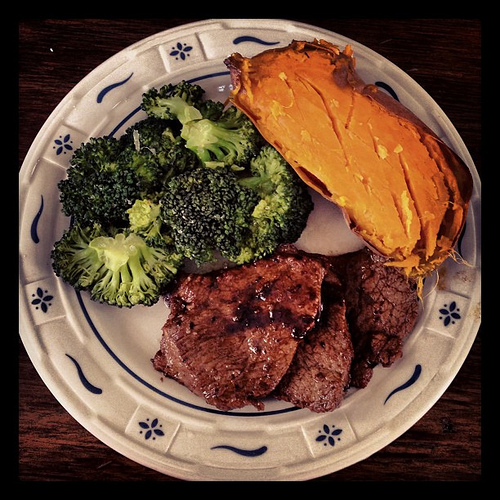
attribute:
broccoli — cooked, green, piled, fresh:
[44, 78, 319, 313]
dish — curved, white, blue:
[17, 16, 488, 486]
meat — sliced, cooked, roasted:
[144, 241, 422, 422]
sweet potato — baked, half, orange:
[220, 30, 478, 286]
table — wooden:
[5, 1, 499, 497]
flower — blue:
[309, 415, 349, 455]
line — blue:
[60, 348, 107, 403]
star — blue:
[28, 283, 58, 318]